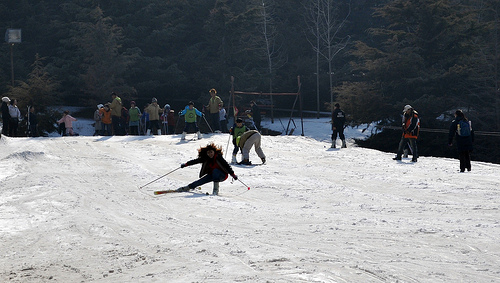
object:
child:
[229, 117, 251, 165]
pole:
[233, 177, 250, 191]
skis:
[236, 177, 251, 190]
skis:
[138, 166, 189, 190]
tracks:
[0, 143, 500, 283]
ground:
[0, 105, 500, 283]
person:
[449, 107, 477, 173]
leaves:
[326, 0, 500, 123]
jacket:
[401, 110, 420, 139]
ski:
[205, 187, 220, 195]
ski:
[153, 188, 176, 195]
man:
[331, 102, 349, 148]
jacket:
[99, 108, 112, 124]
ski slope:
[0, 135, 500, 283]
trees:
[0, 0, 286, 114]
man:
[390, 104, 419, 163]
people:
[0, 87, 264, 140]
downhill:
[0, 133, 500, 283]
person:
[174, 140, 238, 195]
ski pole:
[140, 163, 182, 192]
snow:
[0, 105, 500, 283]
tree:
[292, 0, 356, 119]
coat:
[401, 110, 421, 139]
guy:
[232, 129, 266, 165]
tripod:
[226, 75, 306, 135]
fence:
[242, 107, 332, 136]